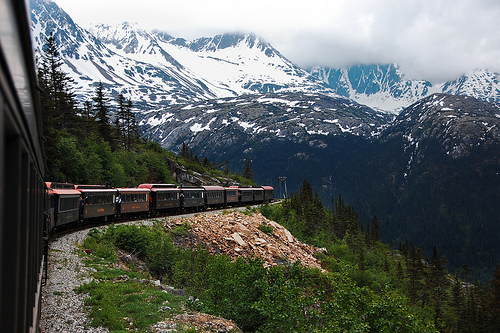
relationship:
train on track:
[51, 177, 271, 210] [63, 200, 277, 231]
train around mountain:
[51, 177, 271, 210] [99, 126, 428, 332]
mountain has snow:
[43, 2, 310, 123] [179, 46, 277, 88]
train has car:
[51, 177, 271, 210] [79, 185, 120, 224]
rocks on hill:
[200, 218, 326, 280] [99, 126, 428, 332]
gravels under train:
[47, 244, 88, 331] [51, 177, 271, 210]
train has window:
[51, 177, 271, 210] [119, 194, 127, 202]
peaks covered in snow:
[98, 14, 272, 61] [179, 46, 277, 88]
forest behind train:
[46, 84, 235, 184] [51, 177, 271, 210]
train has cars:
[51, 177, 271, 210] [80, 189, 151, 216]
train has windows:
[51, 177, 271, 210] [86, 195, 116, 204]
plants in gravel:
[82, 231, 125, 331] [47, 244, 88, 331]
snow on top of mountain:
[179, 46, 277, 88] [99, 126, 428, 332]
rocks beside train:
[200, 218, 326, 280] [51, 177, 271, 210]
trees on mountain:
[115, 91, 139, 140] [99, 126, 428, 332]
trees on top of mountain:
[34, 62, 269, 188] [99, 126, 428, 332]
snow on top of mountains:
[179, 46, 277, 88] [31, 2, 291, 77]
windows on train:
[86, 195, 116, 204] [51, 177, 271, 210]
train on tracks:
[51, 177, 271, 210] [63, 200, 277, 231]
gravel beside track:
[47, 244, 88, 331] [41, 200, 276, 238]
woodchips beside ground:
[177, 219, 301, 256] [150, 219, 343, 270]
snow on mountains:
[179, 46, 277, 88] [31, 2, 291, 77]